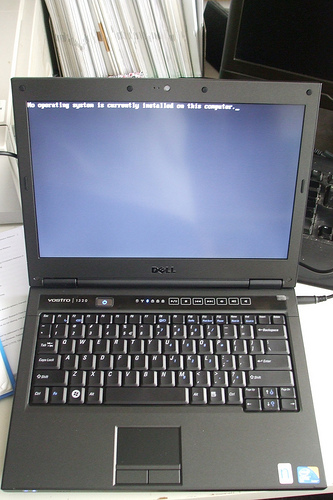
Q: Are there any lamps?
A: No, there are no lamps.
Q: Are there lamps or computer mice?
A: No, there are no lamps or computer mice.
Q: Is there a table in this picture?
A: Yes, there is a table.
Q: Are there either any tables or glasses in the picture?
A: Yes, there is a table.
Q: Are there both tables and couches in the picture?
A: No, there is a table but no couches.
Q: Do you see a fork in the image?
A: No, there are no forks.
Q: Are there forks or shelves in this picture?
A: No, there are no forks or shelves.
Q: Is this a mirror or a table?
A: This is a table.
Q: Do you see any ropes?
A: No, there are no ropes.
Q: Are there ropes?
A: No, there are no ropes.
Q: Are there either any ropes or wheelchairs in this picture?
A: No, there are no ropes or wheelchairs.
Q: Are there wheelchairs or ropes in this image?
A: No, there are no ropes or wheelchairs.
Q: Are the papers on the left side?
A: Yes, the papers are on the left of the image.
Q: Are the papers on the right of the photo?
A: No, the papers are on the left of the image.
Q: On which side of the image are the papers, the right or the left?
A: The papers are on the left of the image.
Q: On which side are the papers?
A: The papers are on the left of the image.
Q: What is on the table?
A: The papers are on the table.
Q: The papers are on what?
A: The papers are on the table.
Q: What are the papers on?
A: The papers are on the table.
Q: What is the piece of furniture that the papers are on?
A: The piece of furniture is a table.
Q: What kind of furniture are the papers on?
A: The papers are on the table.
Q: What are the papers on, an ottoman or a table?
A: The papers are on a table.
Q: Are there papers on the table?
A: Yes, there are papers on the table.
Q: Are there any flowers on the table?
A: No, there are papers on the table.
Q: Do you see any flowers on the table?
A: No, there are papers on the table.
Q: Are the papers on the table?
A: Yes, the papers are on the table.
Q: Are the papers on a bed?
A: No, the papers are on the table.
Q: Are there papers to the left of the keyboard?
A: Yes, there are papers to the left of the keyboard.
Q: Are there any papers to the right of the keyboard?
A: No, the papers are to the left of the keyboard.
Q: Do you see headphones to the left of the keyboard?
A: No, there are papers to the left of the keyboard.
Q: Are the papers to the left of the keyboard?
A: Yes, the papers are to the left of the keyboard.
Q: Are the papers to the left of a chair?
A: No, the papers are to the left of the keyboard.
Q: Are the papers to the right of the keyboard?
A: No, the papers are to the left of the keyboard.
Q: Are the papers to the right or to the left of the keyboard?
A: The papers are to the left of the keyboard.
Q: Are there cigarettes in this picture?
A: No, there are no cigarettes.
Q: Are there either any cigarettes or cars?
A: No, there are no cigarettes or cars.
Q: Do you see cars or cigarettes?
A: No, there are no cigarettes or cars.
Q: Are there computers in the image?
A: Yes, there is a computer.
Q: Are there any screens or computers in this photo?
A: Yes, there is a computer.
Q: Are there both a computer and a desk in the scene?
A: Yes, there are both a computer and a desk.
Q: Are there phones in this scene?
A: No, there are no phones.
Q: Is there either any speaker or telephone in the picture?
A: No, there are no phones or speakers.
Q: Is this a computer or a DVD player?
A: This is a computer.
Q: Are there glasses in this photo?
A: No, there are no glasses.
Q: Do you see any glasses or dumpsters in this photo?
A: No, there are no glasses or dumpsters.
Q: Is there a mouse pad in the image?
A: Yes, there is a mouse pad.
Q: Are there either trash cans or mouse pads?
A: Yes, there is a mouse pad.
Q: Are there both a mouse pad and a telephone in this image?
A: No, there is a mouse pad but no phones.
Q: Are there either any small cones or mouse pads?
A: Yes, there is a small mouse pad.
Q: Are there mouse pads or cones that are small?
A: Yes, the mouse pad is small.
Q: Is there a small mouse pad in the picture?
A: Yes, there is a small mouse pad.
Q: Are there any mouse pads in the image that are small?
A: Yes, there is a mouse pad that is small.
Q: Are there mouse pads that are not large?
A: Yes, there is a small mouse pad.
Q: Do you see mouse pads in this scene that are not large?
A: Yes, there is a small mouse pad.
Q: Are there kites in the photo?
A: No, there are no kites.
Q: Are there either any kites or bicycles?
A: No, there are no kites or bicycles.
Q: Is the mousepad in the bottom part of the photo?
A: Yes, the mousepad is in the bottom of the image.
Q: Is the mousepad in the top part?
A: No, the mousepad is in the bottom of the image.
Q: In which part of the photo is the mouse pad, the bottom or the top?
A: The mouse pad is in the bottom of the image.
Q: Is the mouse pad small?
A: Yes, the mouse pad is small.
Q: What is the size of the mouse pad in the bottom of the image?
A: The mouse pad is small.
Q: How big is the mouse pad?
A: The mouse pad is small.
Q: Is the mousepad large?
A: No, the mousepad is small.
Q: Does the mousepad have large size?
A: No, the mousepad is small.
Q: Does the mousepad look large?
A: No, the mousepad is small.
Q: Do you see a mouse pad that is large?
A: No, there is a mouse pad but it is small.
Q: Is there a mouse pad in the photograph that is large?
A: No, there is a mouse pad but it is small.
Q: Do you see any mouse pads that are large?
A: No, there is a mouse pad but it is small.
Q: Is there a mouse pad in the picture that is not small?
A: No, there is a mouse pad but it is small.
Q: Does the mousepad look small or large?
A: The mousepad is small.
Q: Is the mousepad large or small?
A: The mousepad is small.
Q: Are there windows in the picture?
A: Yes, there are windows.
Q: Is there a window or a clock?
A: Yes, there are windows.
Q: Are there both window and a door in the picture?
A: No, there are windows but no doors.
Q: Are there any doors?
A: No, there are no doors.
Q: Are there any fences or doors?
A: No, there are no doors or fences.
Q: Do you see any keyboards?
A: Yes, there is a keyboard.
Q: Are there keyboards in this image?
A: Yes, there is a keyboard.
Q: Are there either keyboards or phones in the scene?
A: Yes, there is a keyboard.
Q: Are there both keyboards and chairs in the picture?
A: No, there is a keyboard but no chairs.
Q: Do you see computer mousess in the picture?
A: No, there are no computer mousess.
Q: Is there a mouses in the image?
A: No, there are no computer mousess.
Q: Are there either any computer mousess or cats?
A: No, there are no computer mousess or cats.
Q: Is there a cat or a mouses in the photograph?
A: No, there are no computer mousess or cats.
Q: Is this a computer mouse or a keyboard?
A: This is a keyboard.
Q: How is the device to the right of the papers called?
A: The device is a keyboard.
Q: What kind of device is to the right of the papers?
A: The device is a keyboard.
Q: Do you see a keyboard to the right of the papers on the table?
A: Yes, there is a keyboard to the right of the papers.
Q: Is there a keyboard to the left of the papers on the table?
A: No, the keyboard is to the right of the papers.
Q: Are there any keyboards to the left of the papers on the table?
A: No, the keyboard is to the right of the papers.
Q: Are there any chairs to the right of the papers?
A: No, there is a keyboard to the right of the papers.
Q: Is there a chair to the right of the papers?
A: No, there is a keyboard to the right of the papers.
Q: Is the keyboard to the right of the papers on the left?
A: Yes, the keyboard is to the right of the papers.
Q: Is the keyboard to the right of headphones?
A: No, the keyboard is to the right of the papers.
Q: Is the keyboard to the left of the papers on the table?
A: No, the keyboard is to the right of the papers.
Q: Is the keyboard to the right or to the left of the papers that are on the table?
A: The keyboard is to the right of the papers.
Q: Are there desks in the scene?
A: Yes, there is a desk.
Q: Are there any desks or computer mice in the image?
A: Yes, there is a desk.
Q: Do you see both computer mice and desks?
A: No, there is a desk but no computer mice.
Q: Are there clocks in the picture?
A: No, there are no clocks.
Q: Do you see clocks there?
A: No, there are no clocks.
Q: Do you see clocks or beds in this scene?
A: No, there are no clocks or beds.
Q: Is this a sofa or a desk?
A: This is a desk.